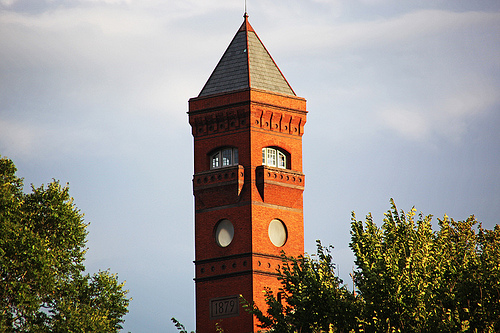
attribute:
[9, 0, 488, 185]
cloud — white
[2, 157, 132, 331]
tree — green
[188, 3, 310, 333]
tower — red, brick, tall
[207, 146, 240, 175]
window — glass, arched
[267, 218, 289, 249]
circle — white, glass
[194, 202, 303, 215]
line — gray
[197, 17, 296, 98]
roof — gray, pointed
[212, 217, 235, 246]
circle — white, glass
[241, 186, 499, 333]
tree — green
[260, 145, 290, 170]
window — glass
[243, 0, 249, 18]
rod — metal